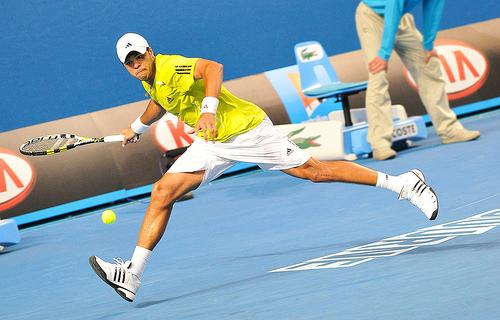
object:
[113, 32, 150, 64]
cap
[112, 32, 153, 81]
head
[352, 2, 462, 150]
pants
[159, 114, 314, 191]
shorts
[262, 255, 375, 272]
letters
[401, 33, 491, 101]
logo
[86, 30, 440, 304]
man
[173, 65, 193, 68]
stripes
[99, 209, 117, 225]
ball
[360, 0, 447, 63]
blue shirt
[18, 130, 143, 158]
racket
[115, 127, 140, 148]
hand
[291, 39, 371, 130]
chair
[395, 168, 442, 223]
shoe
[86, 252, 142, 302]
shoe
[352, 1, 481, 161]
man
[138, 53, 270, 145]
shirt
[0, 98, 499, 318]
tennis court